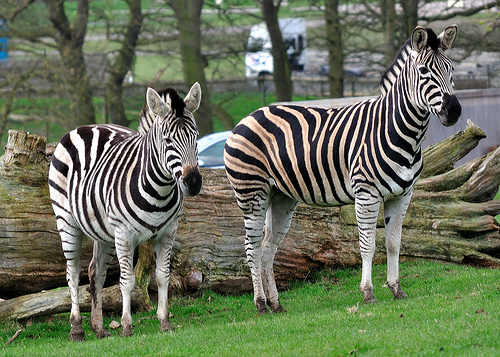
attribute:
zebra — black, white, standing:
[39, 80, 205, 342]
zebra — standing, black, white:
[221, 25, 461, 313]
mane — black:
[421, 20, 440, 57]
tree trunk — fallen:
[2, 126, 496, 336]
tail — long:
[87, 244, 100, 311]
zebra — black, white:
[17, 31, 223, 353]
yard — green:
[11, 263, 496, 353]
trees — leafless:
[21, 34, 476, 135]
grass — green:
[194, 315, 495, 355]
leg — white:
[258, 190, 298, 312]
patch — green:
[0, 255, 499, 355]